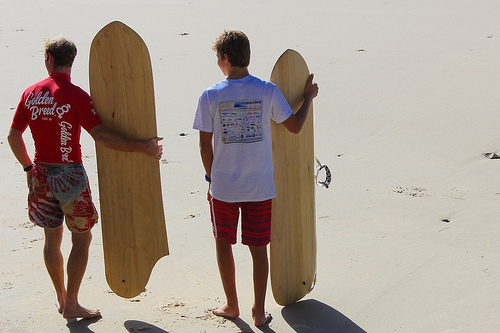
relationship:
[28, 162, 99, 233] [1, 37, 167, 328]
pants on man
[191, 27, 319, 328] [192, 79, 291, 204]
man wears shirt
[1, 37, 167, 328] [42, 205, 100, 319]
man has legs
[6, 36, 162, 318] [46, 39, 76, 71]
man has head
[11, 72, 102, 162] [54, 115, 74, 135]
red shirt with letter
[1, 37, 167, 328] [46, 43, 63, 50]
man has hair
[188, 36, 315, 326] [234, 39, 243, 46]
man has hair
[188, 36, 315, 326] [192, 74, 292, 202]
man wearing t-shirt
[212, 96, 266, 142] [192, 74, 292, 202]
design on t-shirt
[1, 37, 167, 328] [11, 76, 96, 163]
man wearing a red shirt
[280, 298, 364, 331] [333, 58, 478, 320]
shadow on ground